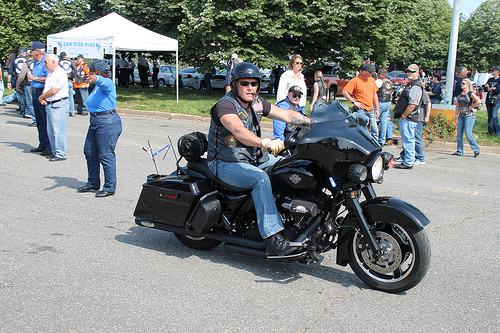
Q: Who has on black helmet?
A: A man.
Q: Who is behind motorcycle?
A: A lady.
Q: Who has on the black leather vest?
A: A man.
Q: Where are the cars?
A: Parking lot.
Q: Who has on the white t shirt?
A: A man.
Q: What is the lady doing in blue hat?
A: Pointing.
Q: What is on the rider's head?
A: Helmet.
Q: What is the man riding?
A: Motorcycle.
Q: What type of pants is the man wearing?
A: Blue jeans.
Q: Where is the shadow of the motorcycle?
A: On the ground.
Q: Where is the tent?
A: In the background to the left.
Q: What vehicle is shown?
A: Motorcycle.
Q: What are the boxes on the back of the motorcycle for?
A: Storage.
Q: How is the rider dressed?
A: Biker style.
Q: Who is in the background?
A: Spectators.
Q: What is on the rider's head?
A: Helmet.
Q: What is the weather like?
A: Fair.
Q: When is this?
A: Afternoon.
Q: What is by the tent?
A: Trees.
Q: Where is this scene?
A: Event.